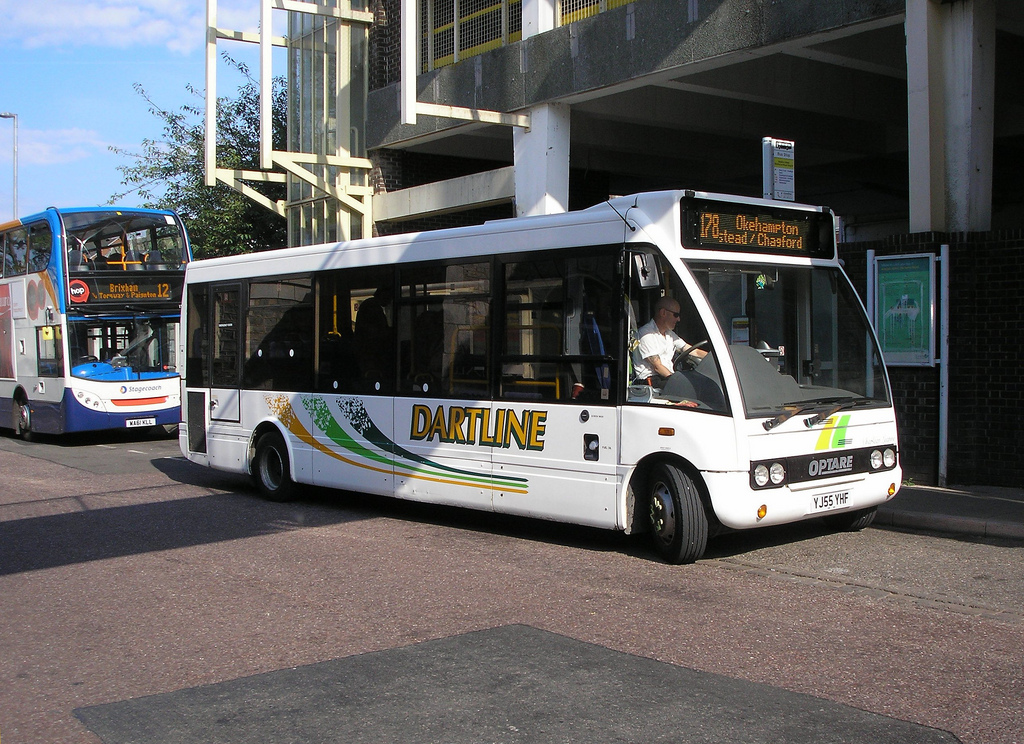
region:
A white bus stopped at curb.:
[169, 194, 906, 555]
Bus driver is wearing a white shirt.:
[634, 294, 717, 411]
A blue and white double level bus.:
[6, 194, 191, 435]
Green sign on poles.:
[871, 254, 958, 471]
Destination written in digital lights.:
[685, 182, 842, 252]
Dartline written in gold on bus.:
[391, 399, 553, 454]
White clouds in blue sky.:
[6, 0, 304, 207]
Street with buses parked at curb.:
[3, 187, 1021, 739]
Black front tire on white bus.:
[635, 460, 709, 568]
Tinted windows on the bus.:
[191, 229, 631, 416]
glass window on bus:
[680, 259, 895, 400]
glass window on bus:
[621, 269, 732, 413]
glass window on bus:
[507, 259, 616, 390]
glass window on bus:
[191, 277, 240, 369]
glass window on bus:
[33, 318, 60, 375]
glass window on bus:
[238, 270, 309, 369]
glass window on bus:
[317, 264, 428, 381]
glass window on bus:
[406, 251, 499, 388]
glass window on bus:
[49, 201, 186, 271]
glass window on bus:
[73, 316, 179, 375]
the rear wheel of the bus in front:
[236, 425, 290, 493]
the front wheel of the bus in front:
[637, 453, 701, 559]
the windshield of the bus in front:
[677, 247, 887, 432]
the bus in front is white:
[165, 178, 905, 559]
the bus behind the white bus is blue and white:
[0, 197, 188, 445]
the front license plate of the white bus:
[801, 481, 850, 511]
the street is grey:
[0, 424, 1016, 734]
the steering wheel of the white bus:
[665, 333, 713, 372]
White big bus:
[171, 186, 906, 567]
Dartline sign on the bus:
[405, 399, 549, 451]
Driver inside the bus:
[171, 187, 908, 567]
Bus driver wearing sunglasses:
[628, 288, 711, 390]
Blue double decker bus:
[0, 200, 190, 441]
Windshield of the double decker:
[50, 206, 194, 383]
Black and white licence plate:
[123, 414, 159, 428]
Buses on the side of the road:
[0, 202, 1015, 738]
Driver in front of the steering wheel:
[626, 291, 713, 396]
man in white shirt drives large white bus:
[630, 298, 704, 382]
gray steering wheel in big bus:
[674, 333, 716, 371]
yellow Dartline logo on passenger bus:
[409, 401, 546, 447]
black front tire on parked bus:
[643, 459, 705, 565]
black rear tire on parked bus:
[250, 431, 288, 492]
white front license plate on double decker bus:
[124, 415, 157, 429]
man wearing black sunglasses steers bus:
[629, 295, 707, 382]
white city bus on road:
[152, 198, 922, 606]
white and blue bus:
[4, 180, 233, 497]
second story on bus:
[5, 193, 221, 343]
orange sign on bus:
[652, 176, 843, 274]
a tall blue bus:
[9, 215, 181, 434]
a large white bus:
[180, 224, 898, 539]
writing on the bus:
[408, 399, 546, 456]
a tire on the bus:
[641, 462, 703, 554]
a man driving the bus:
[635, 288, 696, 393]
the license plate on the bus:
[815, 489, 864, 509]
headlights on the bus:
[753, 463, 786, 484]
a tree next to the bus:
[117, 130, 321, 251]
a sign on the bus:
[688, 203, 832, 262]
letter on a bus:
[401, 398, 434, 446]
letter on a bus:
[427, 399, 454, 441]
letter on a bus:
[442, 398, 466, 447]